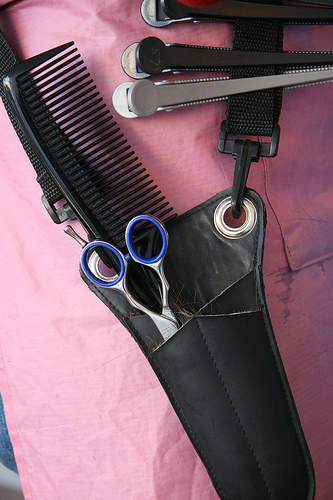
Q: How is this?
A: Kept.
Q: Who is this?
A: No one.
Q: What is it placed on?
A: A clothe.